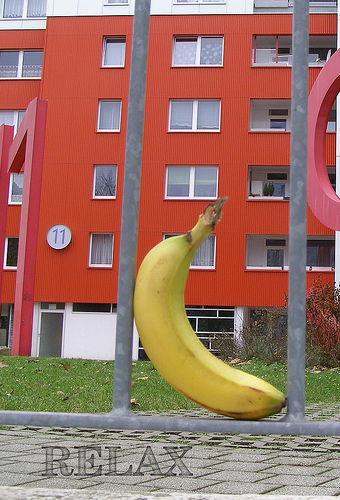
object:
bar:
[288, 1, 307, 420]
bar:
[112, 1, 143, 414]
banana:
[133, 194, 288, 419]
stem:
[181, 198, 234, 251]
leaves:
[314, 282, 339, 343]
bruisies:
[242, 385, 266, 403]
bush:
[263, 183, 276, 197]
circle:
[45, 223, 71, 251]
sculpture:
[0, 94, 51, 355]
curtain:
[173, 41, 195, 62]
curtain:
[200, 41, 221, 63]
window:
[174, 36, 223, 63]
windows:
[89, 232, 111, 265]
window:
[7, 169, 22, 206]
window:
[93, 164, 117, 194]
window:
[165, 164, 218, 197]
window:
[264, 182, 284, 197]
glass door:
[39, 311, 61, 358]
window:
[168, 100, 220, 136]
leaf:
[11, 361, 27, 373]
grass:
[1, 353, 339, 413]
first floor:
[1, 227, 339, 293]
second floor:
[1, 157, 339, 208]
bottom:
[35, 301, 280, 360]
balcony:
[247, 167, 334, 200]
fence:
[1, 3, 339, 436]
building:
[1, 3, 339, 361]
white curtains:
[170, 98, 216, 131]